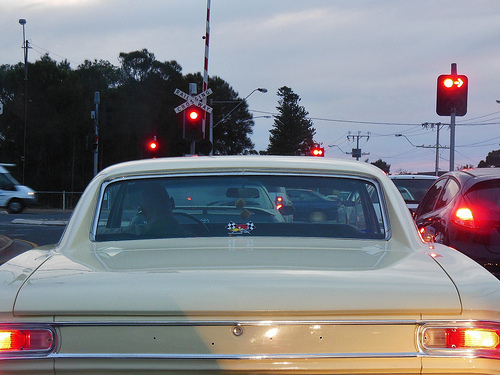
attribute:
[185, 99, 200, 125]
lights — on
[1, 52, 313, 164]
leaves — green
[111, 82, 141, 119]
leaves — green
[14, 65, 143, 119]
leaves — green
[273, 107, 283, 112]
leaf — green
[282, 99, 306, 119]
leaves — green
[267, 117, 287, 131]
leaves — green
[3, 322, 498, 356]
light — on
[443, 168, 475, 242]
light — on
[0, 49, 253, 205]
leaves — green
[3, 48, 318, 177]
leaves — green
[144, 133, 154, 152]
light — on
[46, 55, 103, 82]
leaves — green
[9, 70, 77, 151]
leaves — green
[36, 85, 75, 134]
leaves — green